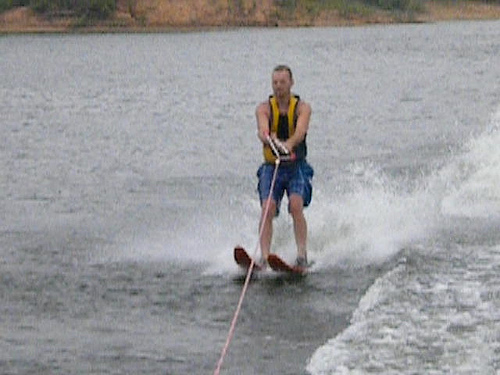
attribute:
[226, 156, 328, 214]
shorts — blue, plaid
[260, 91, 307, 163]
life vest — yellow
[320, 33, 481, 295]
water — temperate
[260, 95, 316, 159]
vest — yellow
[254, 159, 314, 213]
shorts — plaid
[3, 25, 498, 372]
water — wavy, buoyant, splashing, white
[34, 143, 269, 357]
water — dark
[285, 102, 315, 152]
arm — bare 